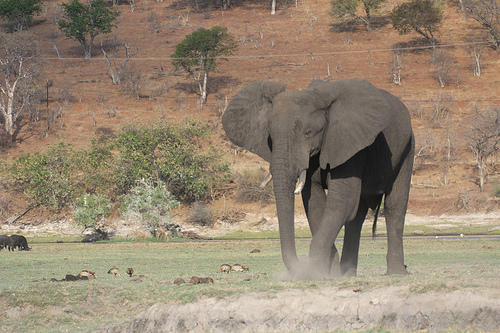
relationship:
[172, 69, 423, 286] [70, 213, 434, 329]
elephant in prairie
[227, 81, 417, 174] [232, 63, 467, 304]
ears on elephant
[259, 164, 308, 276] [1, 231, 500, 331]
trunk touching dirt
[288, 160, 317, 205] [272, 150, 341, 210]
elephant tusk over mouth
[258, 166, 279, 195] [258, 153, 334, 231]
tusk above mouth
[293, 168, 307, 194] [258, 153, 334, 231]
elephant tusk above mouth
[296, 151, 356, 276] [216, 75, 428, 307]
legs of elephant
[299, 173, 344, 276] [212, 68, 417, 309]
foot of elephant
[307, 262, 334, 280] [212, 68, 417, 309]
foot of elephant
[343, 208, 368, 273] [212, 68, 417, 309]
foot of elephant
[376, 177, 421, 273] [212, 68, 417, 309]
foot of elephant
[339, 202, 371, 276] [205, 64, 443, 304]
leg of elephant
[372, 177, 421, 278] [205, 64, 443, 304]
leg of elephant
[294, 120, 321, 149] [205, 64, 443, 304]
eye of elephant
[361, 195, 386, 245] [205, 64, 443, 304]
tail of elephant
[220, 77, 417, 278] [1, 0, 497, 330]
elephant in field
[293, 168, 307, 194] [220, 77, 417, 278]
elephant tusk of elephant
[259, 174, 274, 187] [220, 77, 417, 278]
tusk of elephant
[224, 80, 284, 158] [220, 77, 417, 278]
ear of elephant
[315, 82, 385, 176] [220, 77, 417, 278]
ear of elephant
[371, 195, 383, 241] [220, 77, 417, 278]
tail of elephant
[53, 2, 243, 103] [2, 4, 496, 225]
trees on hill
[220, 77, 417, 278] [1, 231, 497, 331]
elephant in dirt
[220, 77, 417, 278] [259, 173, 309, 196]
elephant has tusk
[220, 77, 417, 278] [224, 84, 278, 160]
elephant has ear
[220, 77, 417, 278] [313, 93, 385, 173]
elephant has ear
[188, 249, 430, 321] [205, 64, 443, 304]
dust with elephant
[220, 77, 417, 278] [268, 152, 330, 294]
elephant with trunk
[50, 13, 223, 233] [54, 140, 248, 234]
hill with brush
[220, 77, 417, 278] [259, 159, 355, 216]
elephant with tusks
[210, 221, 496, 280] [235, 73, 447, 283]
grass with elephant